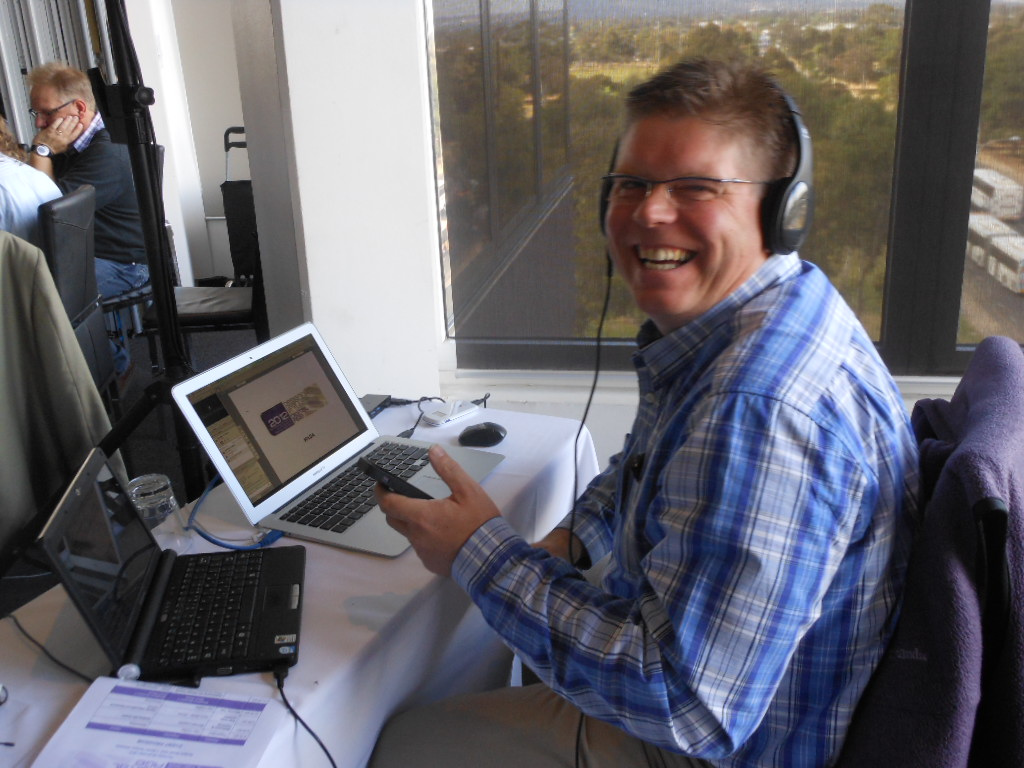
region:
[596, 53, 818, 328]
a man with a headset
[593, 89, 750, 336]
a white man smiling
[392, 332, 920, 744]
checkered blue and white shirt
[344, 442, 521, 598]
a hand holding a mobile phone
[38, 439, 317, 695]
a black notebook laptop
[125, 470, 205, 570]
a glass face down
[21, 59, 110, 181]
a man holding his cheeks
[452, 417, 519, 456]
a wireless computer mouse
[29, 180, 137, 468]
the back rest of a chair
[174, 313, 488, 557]
a white laptop computer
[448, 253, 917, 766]
buttoned down plaid shirt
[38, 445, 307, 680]
interior of open laptop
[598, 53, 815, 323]
headphones on man's head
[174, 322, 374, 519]
image on laptop screen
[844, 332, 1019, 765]
clothing over chair back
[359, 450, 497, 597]
phone in man's hand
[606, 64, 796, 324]
glasses on man's face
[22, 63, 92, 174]
man with hand on face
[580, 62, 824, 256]
man wearing head phones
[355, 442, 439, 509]
man holding a cell phone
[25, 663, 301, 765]
piece of paper beside laptop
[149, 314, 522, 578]
laptop on right is silver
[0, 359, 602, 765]
tablecloth on the table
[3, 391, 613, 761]
tablecloth on table is white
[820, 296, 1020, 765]
man's jacket on chair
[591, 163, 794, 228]
man wearing pair of eyeglasses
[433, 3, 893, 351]
building has a window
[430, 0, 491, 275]
building has a window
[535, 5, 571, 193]
building has a window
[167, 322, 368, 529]
laptop has a screen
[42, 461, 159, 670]
laptop has a screen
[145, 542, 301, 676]
laptop has a keyboard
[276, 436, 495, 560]
laptop has a keyboard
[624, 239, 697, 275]
man has all his teeth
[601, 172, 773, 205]
glasses are small and meta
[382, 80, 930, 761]
man is wearing a laughing smile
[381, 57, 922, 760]
man is wearing a headset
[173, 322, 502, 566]
laptop is silver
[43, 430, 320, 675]
laptop is black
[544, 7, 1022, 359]
trees all outside the window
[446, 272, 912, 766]
shirt is blue and gray striped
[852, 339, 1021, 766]
jacket is on the back of the chair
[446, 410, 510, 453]
mouse for the laptop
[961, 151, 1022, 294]
train cars outside the window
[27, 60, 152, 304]
man has head in hand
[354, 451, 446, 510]
device in a man's hand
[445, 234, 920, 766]
blue plaid patterned shirt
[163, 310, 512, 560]
silver laptop on a table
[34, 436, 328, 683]
black laptop on a table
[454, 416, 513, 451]
black mouse on a table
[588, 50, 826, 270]
headphones on a man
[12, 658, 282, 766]
booklet on a white table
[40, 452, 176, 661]
screen on a black laptop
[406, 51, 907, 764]
man wearing a blue shirt and headphones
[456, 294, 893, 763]
blue shirt the man is wearing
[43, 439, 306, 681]
black laptop on the table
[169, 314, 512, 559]
white laptop on the table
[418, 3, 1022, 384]
window behind a man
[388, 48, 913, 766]
a person is sitting down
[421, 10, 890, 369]
a window on a building